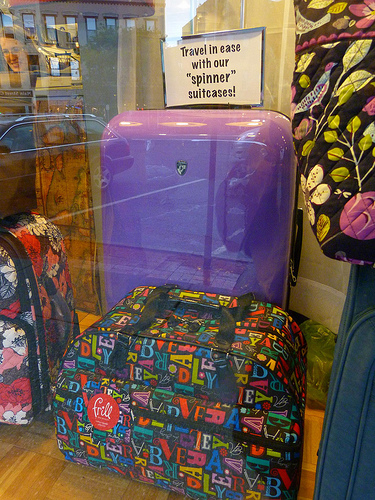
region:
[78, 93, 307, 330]
purple suitcase behind glass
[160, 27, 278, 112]
white and black sign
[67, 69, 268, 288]
reflection on glass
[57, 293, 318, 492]
suitcase with letters on it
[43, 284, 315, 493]
multicolored suitcase with black handles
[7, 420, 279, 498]
wooden floors behind glass case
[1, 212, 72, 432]
pink and white flowers on suitcase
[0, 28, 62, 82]
womans face in background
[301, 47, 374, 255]
green and black design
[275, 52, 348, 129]
bird printed on fabric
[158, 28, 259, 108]
white sign with black print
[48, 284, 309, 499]
large bag with a colorfull all over letter print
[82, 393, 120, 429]
round frill label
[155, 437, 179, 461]
the letter V printed in red on a black luggage bag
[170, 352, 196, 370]
the letter A printed in yellow on a black luggage bag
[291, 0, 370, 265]
floral and bird print black bag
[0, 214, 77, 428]
red white and pink floral bag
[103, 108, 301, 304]
purple suitcase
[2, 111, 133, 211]
car reflecting on a window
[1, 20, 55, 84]
blonde haired woman wearing glasses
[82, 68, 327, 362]
the suitcase is purple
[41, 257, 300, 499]
the suitcase has different letters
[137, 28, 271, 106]
sign is black and white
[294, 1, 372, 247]
the bag has flowers on it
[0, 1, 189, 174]
reflection of building on window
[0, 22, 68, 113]
woman's face on window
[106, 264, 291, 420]
bag straps are black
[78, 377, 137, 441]
red tag on the bag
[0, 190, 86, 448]
suitcase has flowers on it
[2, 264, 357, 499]
the floor is made of wood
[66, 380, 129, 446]
a sticker on a case.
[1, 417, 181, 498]
a section of a wood floor.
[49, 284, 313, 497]
a large colorful case.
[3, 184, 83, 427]
a colorful container.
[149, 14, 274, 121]
a sign on a wall.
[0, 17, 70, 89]
a person's face.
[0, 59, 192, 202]
a parked car.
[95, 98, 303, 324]
a purple case.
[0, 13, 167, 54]
windows on the side of a building.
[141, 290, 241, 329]
a black handle.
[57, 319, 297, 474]
colorful suicase with letters all over it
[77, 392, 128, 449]
red sign with white letters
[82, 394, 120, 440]
sign that says frill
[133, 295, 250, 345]
blck straps of a bag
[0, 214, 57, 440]
flower print piece of luggage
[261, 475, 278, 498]
a blue letter b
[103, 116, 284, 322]
a shiny purple suitcase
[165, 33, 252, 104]
white sign with black letters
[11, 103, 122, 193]
reflection of a car in window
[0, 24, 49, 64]
reflection of person in window